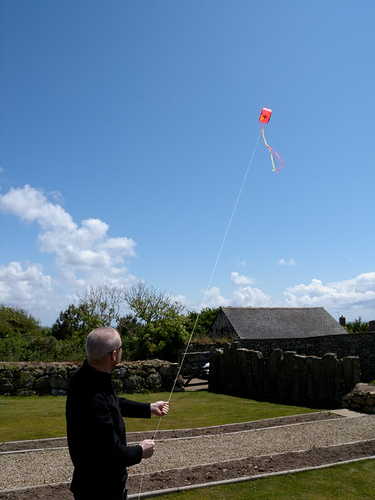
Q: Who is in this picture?
A: A man.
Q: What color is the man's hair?
A: Gray.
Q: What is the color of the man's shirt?
A: Black.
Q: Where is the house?
A: Behind the fences.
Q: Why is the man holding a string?
A: It's a kite on the end.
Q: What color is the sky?
A: Blue.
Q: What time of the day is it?
A: Mid-Afternoon.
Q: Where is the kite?
A: In the sky.